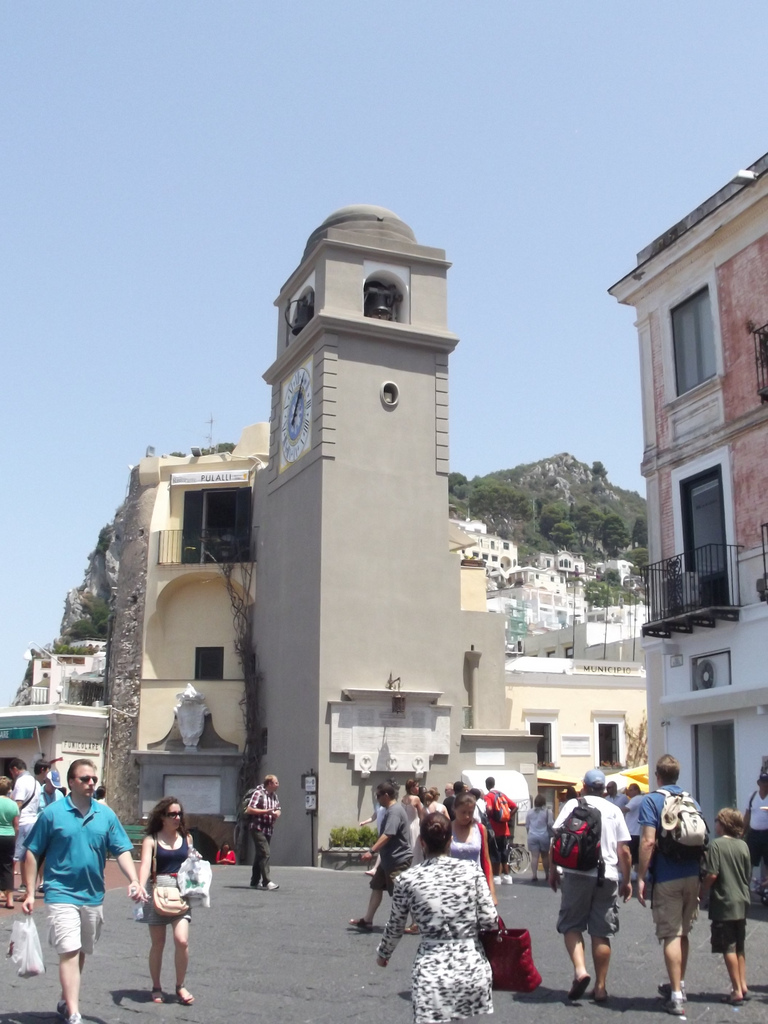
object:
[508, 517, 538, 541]
leaves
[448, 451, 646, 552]
trees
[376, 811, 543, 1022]
person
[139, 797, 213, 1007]
person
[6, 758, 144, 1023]
person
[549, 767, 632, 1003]
person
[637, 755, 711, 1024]
person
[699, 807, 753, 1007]
person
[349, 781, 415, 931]
person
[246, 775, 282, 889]
person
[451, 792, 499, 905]
person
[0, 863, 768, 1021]
ground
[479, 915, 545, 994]
purse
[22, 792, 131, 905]
shirt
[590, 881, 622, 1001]
leg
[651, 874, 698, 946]
shorts